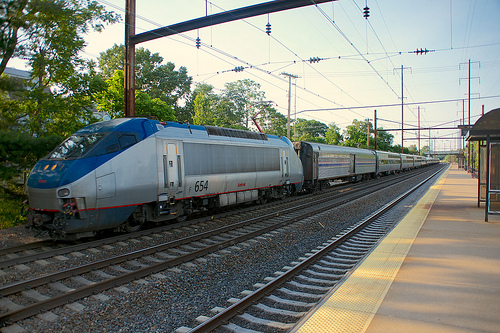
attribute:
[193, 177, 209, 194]
numbers — black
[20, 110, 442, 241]
train — silver, gray, blue, grey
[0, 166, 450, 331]
tracks — long, metal, gray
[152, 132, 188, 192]
door — metal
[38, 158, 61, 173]
lights — orange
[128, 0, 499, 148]
wires — metal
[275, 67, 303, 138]
pole — grey, metal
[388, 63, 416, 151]
pole — grey, metal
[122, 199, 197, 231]
wheels — black, metal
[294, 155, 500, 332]
platform — yellow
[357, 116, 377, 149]
pole — wood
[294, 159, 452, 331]
tile — yellow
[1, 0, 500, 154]
sky — blue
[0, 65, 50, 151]
building — tall